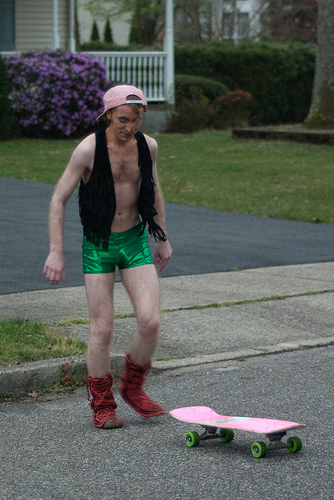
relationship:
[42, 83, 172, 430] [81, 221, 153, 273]
man wearing shorts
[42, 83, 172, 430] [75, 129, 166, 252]
man wearing vest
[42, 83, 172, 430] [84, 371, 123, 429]
man wearing boot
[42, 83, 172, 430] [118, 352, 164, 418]
man wearing boot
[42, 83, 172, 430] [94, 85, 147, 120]
man wearing hat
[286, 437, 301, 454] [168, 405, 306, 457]
front wheel of skateboard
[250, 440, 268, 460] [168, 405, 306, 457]
front wheel of skateboard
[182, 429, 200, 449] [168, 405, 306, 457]
back wheel of skateboard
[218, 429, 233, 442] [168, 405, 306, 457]
back wheel of skateboard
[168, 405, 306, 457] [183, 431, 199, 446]
skateboard attached to wheel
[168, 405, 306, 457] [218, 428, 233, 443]
skateboard attached to back wheel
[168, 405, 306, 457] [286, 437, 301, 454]
skateboard attached to front wheel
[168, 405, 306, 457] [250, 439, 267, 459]
skateboard attached to wheel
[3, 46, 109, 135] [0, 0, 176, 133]
flower bush in front of house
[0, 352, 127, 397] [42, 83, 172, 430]
curb behind man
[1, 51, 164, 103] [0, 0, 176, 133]
porch of house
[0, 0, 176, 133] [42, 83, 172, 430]
house behind man